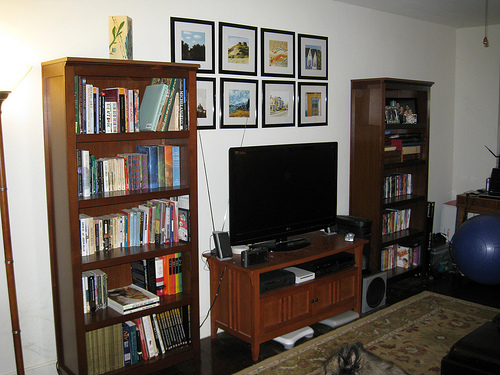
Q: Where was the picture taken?
A: In a living room.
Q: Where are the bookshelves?
A: On both sides of the tv.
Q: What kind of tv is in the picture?
A: Flat screen.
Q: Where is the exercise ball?
A: On the right side.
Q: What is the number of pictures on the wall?
A: Eight.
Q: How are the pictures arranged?
A: In two rows.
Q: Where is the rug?
A: On the floor.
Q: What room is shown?
A: Living room.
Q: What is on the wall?
A: Photos.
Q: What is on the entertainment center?
A: Tv.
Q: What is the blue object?
A: Exercise ball.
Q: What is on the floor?
A: Rug.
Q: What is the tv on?
A: Shelf.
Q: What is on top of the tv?
A: Candle.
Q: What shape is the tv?
A: Rectangle.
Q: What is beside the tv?
A: Bookshelf.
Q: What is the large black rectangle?
A: TV.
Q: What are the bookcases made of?
A: Wood.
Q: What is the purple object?
A: Workout ball.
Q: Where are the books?
A: On shelves.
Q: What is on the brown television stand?
A: A television.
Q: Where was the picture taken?
A: A living room.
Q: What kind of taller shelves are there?
A: Bookshelves.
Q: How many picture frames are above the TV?
A: Eight.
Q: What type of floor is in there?
A: Hardwood.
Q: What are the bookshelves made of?
A: Wood.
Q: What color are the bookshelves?
A: Brown.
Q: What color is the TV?
A: Black.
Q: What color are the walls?
A: White.